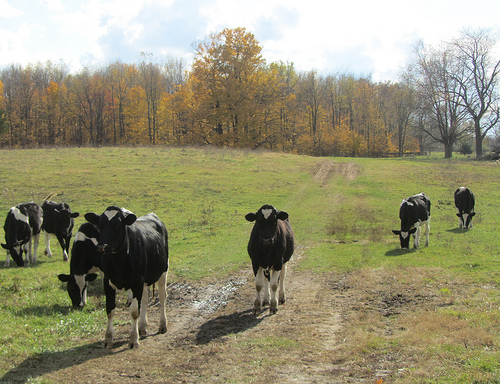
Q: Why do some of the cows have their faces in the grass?
A: Eating.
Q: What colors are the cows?
A: Black & white.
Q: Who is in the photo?
A: No one.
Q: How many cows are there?
A: 7.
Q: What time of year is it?
A: Fall.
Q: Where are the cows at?
A: Field.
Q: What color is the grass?
A: Green.